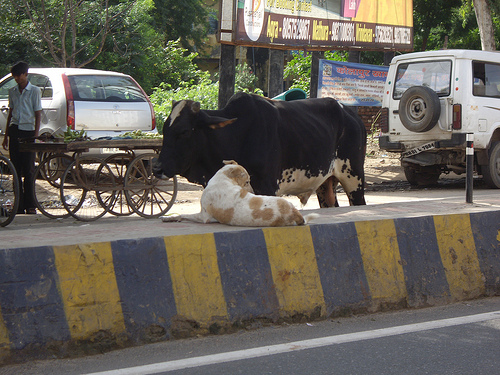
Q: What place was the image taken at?
A: It was taken at the sidewalk.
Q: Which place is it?
A: It is a sidewalk.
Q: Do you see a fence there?
A: No, there are no fences.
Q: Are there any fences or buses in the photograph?
A: No, there are no fences or buses.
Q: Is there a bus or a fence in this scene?
A: No, there are no fences or buses.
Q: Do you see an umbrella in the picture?
A: No, there are no umbrellas.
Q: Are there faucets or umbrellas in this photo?
A: No, there are no umbrellas or faucets.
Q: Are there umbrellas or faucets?
A: No, there are no umbrellas or faucets.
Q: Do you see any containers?
A: No, there are no containers.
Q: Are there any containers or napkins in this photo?
A: No, there are no containers or napkins.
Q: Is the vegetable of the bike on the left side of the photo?
A: Yes, the vegetable is on the left of the image.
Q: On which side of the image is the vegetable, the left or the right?
A: The vegetable is on the left of the image.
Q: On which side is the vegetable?
A: The vegetable is on the left of the image.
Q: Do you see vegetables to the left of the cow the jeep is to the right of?
A: Yes, there is a vegetable to the left of the cow.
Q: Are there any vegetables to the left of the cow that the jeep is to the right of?
A: Yes, there is a vegetable to the left of the cow.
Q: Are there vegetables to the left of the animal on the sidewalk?
A: Yes, there is a vegetable to the left of the cow.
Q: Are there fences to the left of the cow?
A: No, there is a vegetable to the left of the cow.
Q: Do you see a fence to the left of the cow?
A: No, there is a vegetable to the left of the cow.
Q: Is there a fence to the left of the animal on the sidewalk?
A: No, there is a vegetable to the left of the cow.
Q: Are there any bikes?
A: Yes, there is a bike.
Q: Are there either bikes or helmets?
A: Yes, there is a bike.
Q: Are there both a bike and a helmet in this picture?
A: No, there is a bike but no helmets.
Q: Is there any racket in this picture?
A: No, there are no rackets.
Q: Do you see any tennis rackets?
A: No, there are no tennis rackets.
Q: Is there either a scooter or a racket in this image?
A: No, there are no rackets or scooters.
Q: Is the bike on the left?
A: Yes, the bike is on the left of the image.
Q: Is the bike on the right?
A: No, the bike is on the left of the image.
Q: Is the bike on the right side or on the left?
A: The bike is on the left of the image.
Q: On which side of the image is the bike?
A: The bike is on the left of the image.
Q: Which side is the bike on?
A: The bike is on the left of the image.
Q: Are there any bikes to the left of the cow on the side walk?
A: Yes, there is a bike to the left of the cow.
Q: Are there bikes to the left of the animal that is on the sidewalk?
A: Yes, there is a bike to the left of the cow.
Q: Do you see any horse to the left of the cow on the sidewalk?
A: No, there is a bike to the left of the cow.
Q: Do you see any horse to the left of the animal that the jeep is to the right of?
A: No, there is a bike to the left of the cow.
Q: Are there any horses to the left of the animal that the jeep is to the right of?
A: No, there is a bike to the left of the cow.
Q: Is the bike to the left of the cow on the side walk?
A: Yes, the bike is to the left of the cow.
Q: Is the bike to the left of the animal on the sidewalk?
A: Yes, the bike is to the left of the cow.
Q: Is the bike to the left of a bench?
A: No, the bike is to the left of the cow.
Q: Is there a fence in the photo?
A: No, there are no fences.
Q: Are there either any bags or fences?
A: No, there are no fences or bags.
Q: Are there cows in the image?
A: Yes, there is a cow.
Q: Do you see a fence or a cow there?
A: Yes, there is a cow.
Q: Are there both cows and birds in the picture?
A: No, there is a cow but no birds.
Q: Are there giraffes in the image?
A: No, there are no giraffes.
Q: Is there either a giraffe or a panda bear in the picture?
A: No, there are no giraffes or panda bears.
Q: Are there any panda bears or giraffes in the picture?
A: No, there are no giraffes or panda bears.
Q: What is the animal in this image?
A: The animal is a cow.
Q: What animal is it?
A: The animal is a cow.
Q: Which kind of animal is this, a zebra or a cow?
A: This is a cow.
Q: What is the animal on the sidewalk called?
A: The animal is a cow.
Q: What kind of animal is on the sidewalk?
A: The animal is a cow.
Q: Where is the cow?
A: The cow is on the sidewalk.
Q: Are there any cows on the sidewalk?
A: Yes, there is a cow on the sidewalk.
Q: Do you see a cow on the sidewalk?
A: Yes, there is a cow on the sidewalk.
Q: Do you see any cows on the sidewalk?
A: Yes, there is a cow on the sidewalk.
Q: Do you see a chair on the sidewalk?
A: No, there is a cow on the sidewalk.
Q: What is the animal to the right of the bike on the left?
A: The animal is a cow.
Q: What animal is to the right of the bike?
A: The animal is a cow.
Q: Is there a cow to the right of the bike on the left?
A: Yes, there is a cow to the right of the bike.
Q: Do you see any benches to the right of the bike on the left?
A: No, there is a cow to the right of the bike.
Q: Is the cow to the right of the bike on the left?
A: Yes, the cow is to the right of the bike.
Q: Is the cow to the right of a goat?
A: No, the cow is to the right of the bike.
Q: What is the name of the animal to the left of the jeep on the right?
A: The animal is a cow.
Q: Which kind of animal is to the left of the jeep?
A: The animal is a cow.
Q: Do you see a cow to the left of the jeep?
A: Yes, there is a cow to the left of the jeep.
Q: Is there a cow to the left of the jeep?
A: Yes, there is a cow to the left of the jeep.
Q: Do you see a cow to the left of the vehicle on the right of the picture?
A: Yes, there is a cow to the left of the jeep.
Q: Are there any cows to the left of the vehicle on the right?
A: Yes, there is a cow to the left of the jeep.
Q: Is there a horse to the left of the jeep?
A: No, there is a cow to the left of the jeep.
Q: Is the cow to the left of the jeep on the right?
A: Yes, the cow is to the left of the jeep.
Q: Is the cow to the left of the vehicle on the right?
A: Yes, the cow is to the left of the jeep.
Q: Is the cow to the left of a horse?
A: No, the cow is to the left of the jeep.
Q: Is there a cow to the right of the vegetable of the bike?
A: Yes, there is a cow to the right of the vegetable.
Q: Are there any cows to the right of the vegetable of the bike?
A: Yes, there is a cow to the right of the vegetable.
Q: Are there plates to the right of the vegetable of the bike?
A: No, there is a cow to the right of the vegetable.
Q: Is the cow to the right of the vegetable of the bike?
A: Yes, the cow is to the right of the vegetable.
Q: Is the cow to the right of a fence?
A: No, the cow is to the right of the vegetable.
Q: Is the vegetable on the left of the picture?
A: Yes, the vegetable is on the left of the image.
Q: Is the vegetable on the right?
A: No, the vegetable is on the left of the image.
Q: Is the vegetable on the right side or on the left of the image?
A: The vegetable is on the left of the image.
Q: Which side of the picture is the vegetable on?
A: The vegetable is on the left of the image.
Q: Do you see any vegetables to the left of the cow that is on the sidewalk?
A: Yes, there is a vegetable to the left of the cow.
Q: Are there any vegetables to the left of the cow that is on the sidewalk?
A: Yes, there is a vegetable to the left of the cow.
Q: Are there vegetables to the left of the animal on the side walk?
A: Yes, there is a vegetable to the left of the cow.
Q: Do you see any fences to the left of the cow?
A: No, there is a vegetable to the left of the cow.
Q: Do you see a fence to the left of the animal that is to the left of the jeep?
A: No, there is a vegetable to the left of the cow.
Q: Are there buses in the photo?
A: No, there are no buses.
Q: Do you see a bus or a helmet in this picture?
A: No, there are no buses or helmets.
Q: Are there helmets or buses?
A: No, there are no buses or helmets.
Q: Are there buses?
A: No, there are no buses.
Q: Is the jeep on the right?
A: Yes, the jeep is on the right of the image.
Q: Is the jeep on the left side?
A: No, the jeep is on the right of the image.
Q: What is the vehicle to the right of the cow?
A: The vehicle is a jeep.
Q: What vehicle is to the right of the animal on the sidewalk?
A: The vehicle is a jeep.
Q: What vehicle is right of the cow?
A: The vehicle is a jeep.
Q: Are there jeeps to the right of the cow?
A: Yes, there is a jeep to the right of the cow.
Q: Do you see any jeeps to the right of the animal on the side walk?
A: Yes, there is a jeep to the right of the cow.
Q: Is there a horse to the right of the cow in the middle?
A: No, there is a jeep to the right of the cow.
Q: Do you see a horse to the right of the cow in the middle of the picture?
A: No, there is a jeep to the right of the cow.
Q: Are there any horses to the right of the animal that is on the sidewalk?
A: No, there is a jeep to the right of the cow.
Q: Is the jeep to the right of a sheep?
A: No, the jeep is to the right of a cow.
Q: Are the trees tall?
A: Yes, the trees are tall.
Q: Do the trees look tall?
A: Yes, the trees are tall.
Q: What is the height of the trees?
A: The trees are tall.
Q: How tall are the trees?
A: The trees are tall.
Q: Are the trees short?
A: No, the trees are tall.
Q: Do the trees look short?
A: No, the trees are tall.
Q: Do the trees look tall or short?
A: The trees are tall.